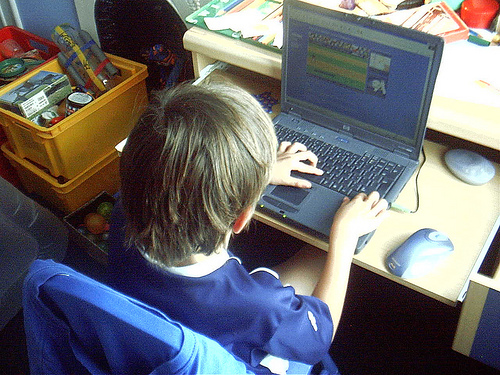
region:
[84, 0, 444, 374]
boy working on laptop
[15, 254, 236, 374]
blue shirt draped on chair back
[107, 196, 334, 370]
blue shirt boy is wearing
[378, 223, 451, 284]
wireless mouse on desk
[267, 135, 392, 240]
boys hands on laptop keyboard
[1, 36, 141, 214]
two yellow bins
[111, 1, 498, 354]
white desk laptop is on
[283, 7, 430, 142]
screen of the laptop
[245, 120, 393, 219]
black keyboard and trackpad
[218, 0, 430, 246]
open laptop on desk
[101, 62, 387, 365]
Young boy sitting at desk typing on computer.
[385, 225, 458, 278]
Computer mouse lying on desk.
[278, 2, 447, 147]
Monitor for laptop computer.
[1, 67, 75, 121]
Paper box inside plastic bin.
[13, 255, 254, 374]
Blue t-shirt on back of chair.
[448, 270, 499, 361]
Edge of book lying on desk.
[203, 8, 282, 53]
Papers lying on desk.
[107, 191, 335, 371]
Young boy dressed in blue and white shirt.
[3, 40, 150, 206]
Two stacked yellow bins.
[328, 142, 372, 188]
Keys on laptop computer keyboard.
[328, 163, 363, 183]
A lap top keyboard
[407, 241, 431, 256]
A computer mouse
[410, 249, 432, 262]
Mouse reflecting light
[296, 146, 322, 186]
Fingers on keyboard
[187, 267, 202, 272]
White collar on vest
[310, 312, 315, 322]
A white mark on the side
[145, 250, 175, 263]
Hair falling on the collar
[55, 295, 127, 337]
Seat covered with sweater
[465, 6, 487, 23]
A red container top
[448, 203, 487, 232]
Light reflecting off desk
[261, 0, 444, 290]
open laptop computer on keyboard pull-out tray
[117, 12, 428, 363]
child using laptop computer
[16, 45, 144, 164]
yellow plastic storage box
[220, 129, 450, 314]
mouse next to computer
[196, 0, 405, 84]
papers on desk behind computer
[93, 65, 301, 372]
child has brown hair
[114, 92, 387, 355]
child wearing blue and white shirt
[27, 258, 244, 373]
blue shirt on back of chair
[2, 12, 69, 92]
red plastic storage container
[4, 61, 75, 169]
box inside yellow container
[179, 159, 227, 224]
hair of a lady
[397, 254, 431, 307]
part of a mouse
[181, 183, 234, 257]
hair of a boy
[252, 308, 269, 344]
part of a shoulser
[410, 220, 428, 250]
part fo a mouse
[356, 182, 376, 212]
part of a hand